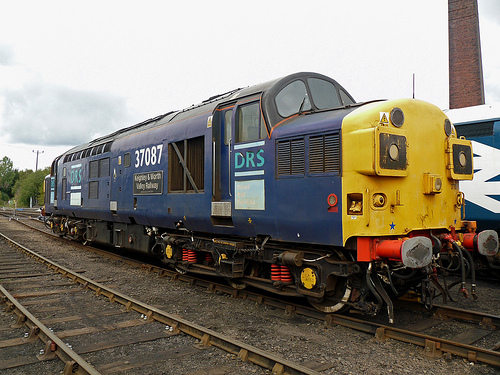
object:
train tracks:
[3, 319, 66, 373]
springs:
[267, 261, 290, 284]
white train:
[442, 101, 499, 283]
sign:
[129, 172, 167, 199]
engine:
[264, 97, 499, 315]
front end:
[341, 97, 473, 247]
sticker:
[377, 110, 389, 124]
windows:
[282, 82, 310, 115]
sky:
[292, 2, 395, 57]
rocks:
[241, 317, 282, 348]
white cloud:
[10, 87, 117, 140]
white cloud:
[0, 20, 29, 73]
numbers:
[133, 145, 163, 166]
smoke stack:
[444, 0, 489, 110]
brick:
[447, 81, 459, 91]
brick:
[465, 73, 476, 80]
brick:
[451, 50, 462, 56]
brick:
[459, 8, 476, 13]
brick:
[466, 93, 478, 103]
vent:
[272, 130, 341, 175]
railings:
[226, 141, 233, 197]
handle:
[211, 142, 220, 204]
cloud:
[7, 20, 33, 36]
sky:
[14, 14, 61, 52]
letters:
[231, 142, 265, 178]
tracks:
[79, 343, 274, 367]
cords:
[350, 259, 395, 322]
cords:
[433, 230, 480, 311]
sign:
[232, 150, 267, 170]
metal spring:
[265, 259, 292, 286]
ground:
[1, 209, 499, 373]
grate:
[306, 131, 342, 177]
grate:
[272, 134, 306, 178]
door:
[210, 101, 235, 213]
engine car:
[40, 70, 479, 324]